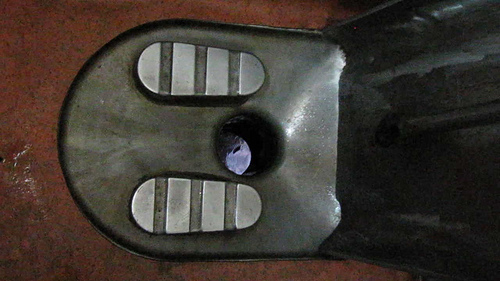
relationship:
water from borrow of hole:
[231, 141, 253, 169] [217, 105, 294, 184]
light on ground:
[280, 86, 321, 142] [8, 5, 494, 279]